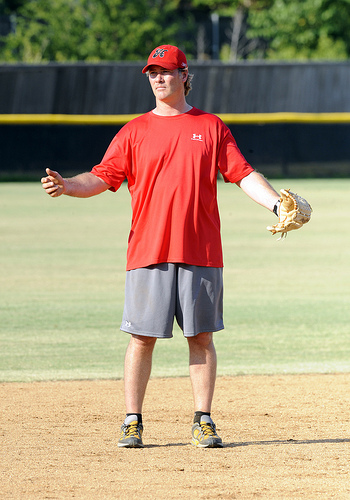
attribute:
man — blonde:
[36, 21, 313, 455]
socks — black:
[123, 412, 215, 424]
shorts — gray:
[119, 243, 230, 342]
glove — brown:
[266, 180, 316, 245]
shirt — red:
[89, 107, 236, 276]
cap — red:
[136, 41, 189, 70]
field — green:
[2, 180, 345, 492]